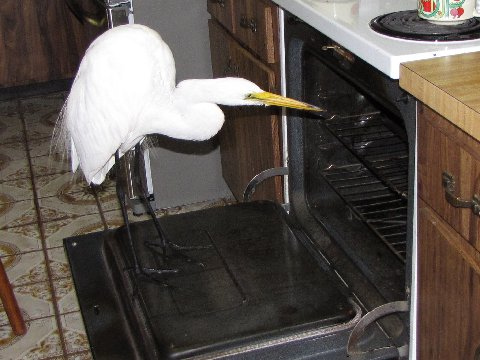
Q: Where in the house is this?
A: The kitchen.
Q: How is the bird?
A: White.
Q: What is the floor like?
A: Tiled.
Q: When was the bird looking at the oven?
A: When the picture was being taken.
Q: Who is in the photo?
A: Nobody.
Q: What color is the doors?
A: Brown.